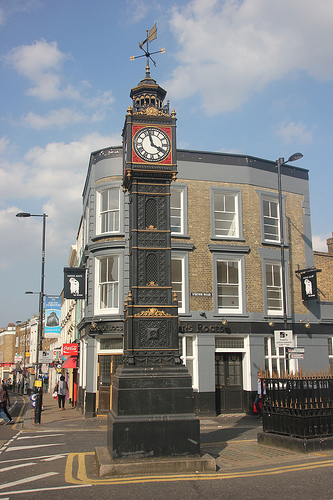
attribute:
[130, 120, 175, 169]
clock — red, white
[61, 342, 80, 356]
logo — coca cola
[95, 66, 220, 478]
pillar — tall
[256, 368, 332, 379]
tips — metal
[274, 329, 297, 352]
sign — black, white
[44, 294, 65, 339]
sign — blue white, black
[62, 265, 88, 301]
sign — black, white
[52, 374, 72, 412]
person — walking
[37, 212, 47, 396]
lightpost — black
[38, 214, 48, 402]
post — black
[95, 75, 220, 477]
tower — monumental, black, gold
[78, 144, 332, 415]
building — brown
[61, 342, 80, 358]
sign — red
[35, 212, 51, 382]
pole — black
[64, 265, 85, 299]
flag — black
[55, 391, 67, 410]
pants — black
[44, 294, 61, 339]
flag — decorative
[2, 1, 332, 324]
sky — blue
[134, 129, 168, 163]
face — white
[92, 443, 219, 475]
pedestal — black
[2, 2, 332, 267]
clouds — white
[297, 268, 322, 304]
banner — black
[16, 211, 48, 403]
street light — metal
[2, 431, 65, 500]
paint — white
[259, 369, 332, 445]
fence — black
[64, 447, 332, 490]
paint — yellow